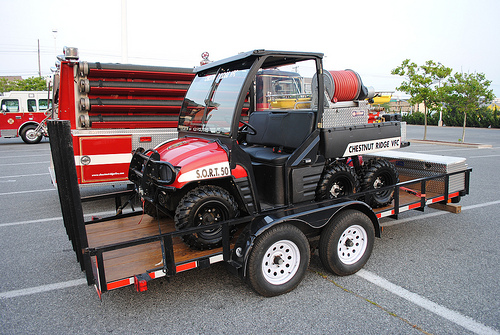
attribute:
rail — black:
[113, 219, 189, 277]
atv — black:
[162, 58, 392, 248]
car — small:
[129, 47, 406, 245]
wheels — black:
[235, 201, 388, 300]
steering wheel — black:
[238, 114, 257, 140]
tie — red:
[394, 178, 425, 196]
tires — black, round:
[245, 220, 312, 297]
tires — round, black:
[317, 207, 376, 277]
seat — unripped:
[236, 110, 267, 157]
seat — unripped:
[256, 112, 318, 159]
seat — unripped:
[244, 113, 286, 155]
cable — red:
[324, 68, 357, 100]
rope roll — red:
[330, 70, 360, 105]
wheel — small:
[359, 155, 399, 203]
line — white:
[393, 271, 482, 332]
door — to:
[0, 98, 19, 136]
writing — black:
[192, 146, 226, 182]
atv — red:
[121, 42, 441, 247]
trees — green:
[390, 57, 492, 145]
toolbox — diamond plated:
[351, 133, 463, 212]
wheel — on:
[245, 220, 309, 298]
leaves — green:
[404, 74, 483, 92]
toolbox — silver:
[317, 94, 369, 128]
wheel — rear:
[355, 156, 404, 210]